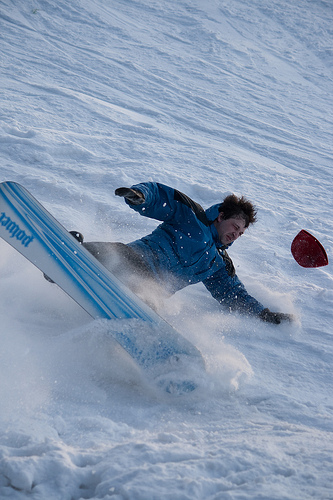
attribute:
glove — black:
[257, 301, 297, 330]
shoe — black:
[68, 226, 88, 247]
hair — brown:
[220, 191, 257, 226]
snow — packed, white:
[1, 1, 331, 496]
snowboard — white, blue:
[3, 176, 210, 409]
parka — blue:
[132, 180, 267, 331]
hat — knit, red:
[287, 225, 330, 276]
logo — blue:
[2, 208, 38, 255]